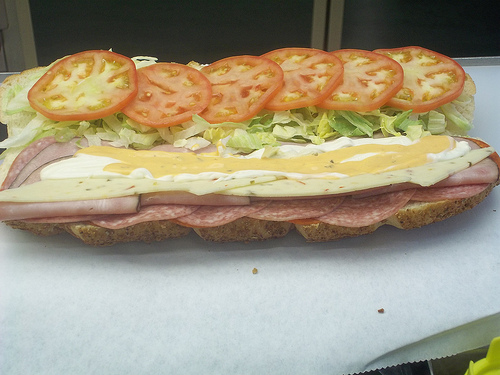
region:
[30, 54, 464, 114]
these are sliced tomatoes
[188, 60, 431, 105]
the tomatoes are red in color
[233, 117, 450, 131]
this is some lettuce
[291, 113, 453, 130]
the lettuce is green in color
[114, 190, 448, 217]
these are pieces of ham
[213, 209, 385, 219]
the ham is red in color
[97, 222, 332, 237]
this is some bread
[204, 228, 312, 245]
the bread is brown in color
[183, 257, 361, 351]
this is a paper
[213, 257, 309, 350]
the paper is white in color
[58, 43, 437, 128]
tomatoes on a sub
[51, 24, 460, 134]
six tomatoes next to each other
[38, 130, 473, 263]
meat and sauce on sandwich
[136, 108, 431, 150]
lettuce underneath the meat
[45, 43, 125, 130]
tomato on end of sandwich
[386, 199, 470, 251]
bread undewr the meat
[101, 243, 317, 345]
white paper that sub is on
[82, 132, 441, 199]
sauce on the sub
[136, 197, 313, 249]
three pieces of meat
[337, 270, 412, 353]
crum on the paper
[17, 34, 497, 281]
a submarine sandwich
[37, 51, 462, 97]
a row of sliced tomatoes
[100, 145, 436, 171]
mustard on a sandwich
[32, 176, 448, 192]
slices of cheese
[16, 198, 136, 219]
a slice of folded ham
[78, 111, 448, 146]
shredded iceberg lettuce on a sandwich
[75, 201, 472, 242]
salami on bread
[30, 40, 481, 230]
a submarine sandwich with meat and veggies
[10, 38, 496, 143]
slice of tomatoes on a bed of salad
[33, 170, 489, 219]
cheese, ham and salami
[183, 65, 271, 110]
the tomatoes are red in color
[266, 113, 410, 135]
this is some lettuce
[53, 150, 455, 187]
this is some cheese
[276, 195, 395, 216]
the ham is red in color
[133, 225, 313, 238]
the bread is brown in color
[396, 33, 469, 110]
tomato on end of sandwich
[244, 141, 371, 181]
sauce on sandwich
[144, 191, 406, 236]
four pieces of meat on sandwich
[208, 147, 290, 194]
yellow and white sauce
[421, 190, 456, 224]
bread under the meat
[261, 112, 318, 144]
green lettuce under the tomatoes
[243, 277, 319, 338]
white paper under the sub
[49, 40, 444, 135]
six tomatoes on sub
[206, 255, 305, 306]
crum on the paper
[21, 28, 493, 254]
sub sanwich on table